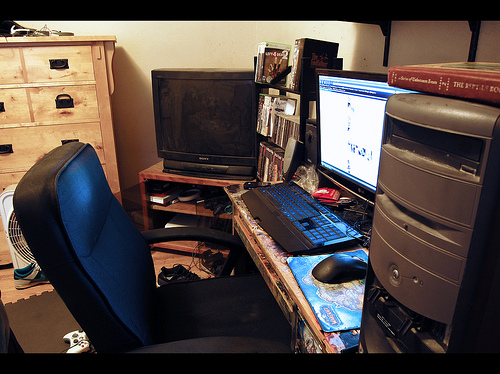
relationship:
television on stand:
[149, 65, 264, 182] [132, 166, 243, 245]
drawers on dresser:
[2, 49, 93, 88] [0, 34, 124, 268]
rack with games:
[140, 196, 229, 241] [151, 191, 178, 204]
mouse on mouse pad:
[315, 250, 362, 285] [283, 248, 375, 334]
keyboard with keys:
[265, 180, 359, 255] [265, 186, 306, 220]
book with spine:
[313, 185, 338, 201] [306, 193, 337, 202]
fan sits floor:
[3, 190, 38, 289] [160, 249, 183, 259]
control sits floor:
[55, 330, 85, 351] [168, 244, 189, 256]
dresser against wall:
[3, 32, 124, 200] [122, 20, 176, 59]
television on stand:
[151, 63, 259, 179] [131, 159, 245, 240]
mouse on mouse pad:
[310, 254, 366, 284] [283, 246, 375, 336]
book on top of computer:
[384, 62, 499, 103] [344, 96, 497, 367]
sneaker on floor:
[12, 261, 52, 295] [2, 248, 212, 368]